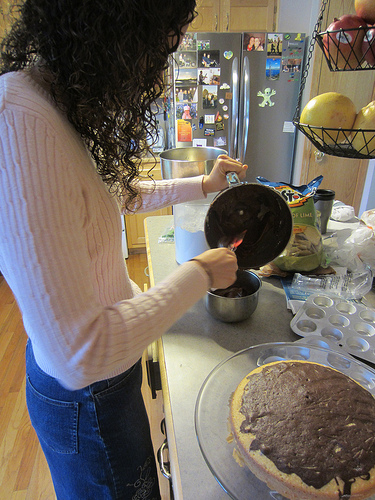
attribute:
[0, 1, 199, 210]
hair — black, curly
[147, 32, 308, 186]
fridge — stainless, large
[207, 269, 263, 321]
bowl — small, silver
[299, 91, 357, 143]
grapefruit — large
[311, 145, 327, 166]
knob — gold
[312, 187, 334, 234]
cup — black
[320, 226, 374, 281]
plastic bag — clear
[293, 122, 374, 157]
basket — black, metal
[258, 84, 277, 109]
decoration — yellow, green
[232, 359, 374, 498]
cake — yellow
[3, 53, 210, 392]
sweater — pink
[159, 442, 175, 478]
pulls — chrome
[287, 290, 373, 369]
pan — steel, silver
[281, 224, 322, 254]
chips — tostitos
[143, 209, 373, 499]
top — silver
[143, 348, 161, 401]
handle — small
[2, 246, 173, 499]
floor — brown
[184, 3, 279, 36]
cabinet — brown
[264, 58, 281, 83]
picture — blue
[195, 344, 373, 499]
dish — glass